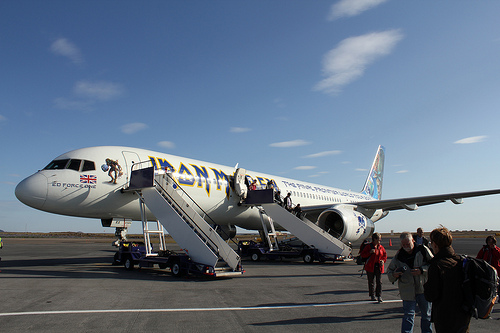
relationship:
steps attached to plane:
[142, 178, 231, 272] [27, 129, 485, 221]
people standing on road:
[363, 217, 495, 325] [75, 266, 105, 288]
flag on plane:
[82, 169, 94, 185] [27, 129, 485, 221]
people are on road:
[363, 217, 495, 325] [75, 266, 105, 288]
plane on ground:
[27, 129, 485, 221] [24, 285, 57, 296]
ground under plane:
[24, 285, 57, 296] [27, 129, 485, 221]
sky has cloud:
[113, 54, 149, 92] [323, 33, 375, 76]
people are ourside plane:
[363, 217, 495, 325] [27, 129, 485, 221]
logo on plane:
[180, 165, 217, 184] [27, 129, 485, 221]